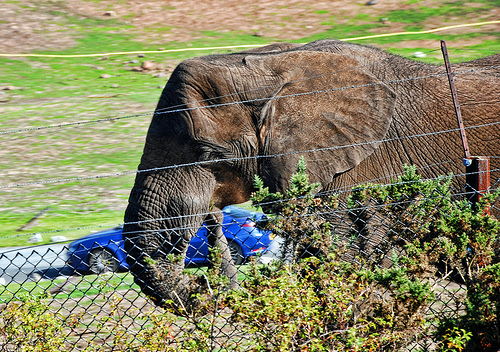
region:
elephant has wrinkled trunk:
[101, 51, 216, 311]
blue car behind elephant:
[77, 207, 257, 270]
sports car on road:
[30, 178, 327, 314]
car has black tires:
[89, 245, 136, 295]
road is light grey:
[15, 242, 93, 294]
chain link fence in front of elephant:
[56, 252, 257, 349]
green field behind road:
[37, 133, 136, 253]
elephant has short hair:
[242, 31, 497, 191]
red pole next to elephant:
[439, 58, 476, 198]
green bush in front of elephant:
[288, 152, 467, 346]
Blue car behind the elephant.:
[63, 206, 272, 266]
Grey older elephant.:
[125, 41, 498, 305]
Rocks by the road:
[26, 230, 66, 249]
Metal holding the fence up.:
[441, 40, 496, 282]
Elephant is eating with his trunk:
[193, 188, 234, 255]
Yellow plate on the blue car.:
[267, 232, 277, 240]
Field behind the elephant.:
[3, 2, 493, 229]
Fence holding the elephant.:
[0, 41, 495, 235]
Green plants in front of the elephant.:
[1, 156, 496, 346]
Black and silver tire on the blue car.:
[85, 245, 119, 276]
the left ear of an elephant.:
[232, 35, 419, 200]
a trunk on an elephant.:
[105, 144, 218, 316]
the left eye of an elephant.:
[197, 122, 237, 190]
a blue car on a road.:
[31, 175, 309, 304]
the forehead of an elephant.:
[136, 49, 267, 168]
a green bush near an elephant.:
[182, 156, 498, 349]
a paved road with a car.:
[0, 250, 300, 267]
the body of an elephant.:
[370, 43, 492, 185]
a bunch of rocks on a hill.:
[88, 33, 188, 105]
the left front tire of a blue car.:
[88, 235, 118, 274]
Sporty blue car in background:
[50, 207, 281, 275]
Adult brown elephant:
[120, 23, 497, 318]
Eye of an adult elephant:
[191, 147, 221, 166]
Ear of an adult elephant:
[241, 57, 402, 203]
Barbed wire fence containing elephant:
[5, 84, 494, 229]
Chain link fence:
[5, 245, 497, 350]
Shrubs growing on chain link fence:
[202, 216, 495, 348]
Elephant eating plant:
[180, 183, 234, 238]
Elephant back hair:
[350, 46, 499, 76]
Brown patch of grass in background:
[5, 14, 67, 49]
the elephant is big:
[103, 33, 494, 310]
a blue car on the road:
[61, 211, 271, 293]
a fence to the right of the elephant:
[27, 195, 473, 335]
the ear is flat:
[222, 28, 397, 178]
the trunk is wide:
[112, 162, 210, 313]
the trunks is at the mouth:
[113, 158, 252, 325]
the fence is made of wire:
[47, 84, 449, 164]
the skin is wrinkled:
[113, 133, 204, 230]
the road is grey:
[12, 239, 70, 276]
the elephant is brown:
[183, 45, 489, 240]